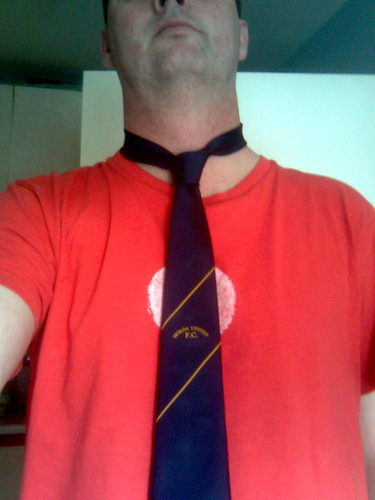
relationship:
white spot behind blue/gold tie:
[145, 265, 243, 334] [119, 122, 247, 500]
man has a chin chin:
[0, 0, 371, 498] [132, 46, 233, 92]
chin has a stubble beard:
[132, 46, 233, 92] [138, 71, 183, 86]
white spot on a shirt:
[145, 259, 237, 331] [2, 156, 372, 498]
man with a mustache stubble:
[0, 0, 371, 498] [137, 6, 208, 36]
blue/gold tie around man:
[119, 122, 247, 500] [0, 0, 371, 498]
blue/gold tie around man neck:
[119, 122, 247, 500] [99, 74, 268, 187]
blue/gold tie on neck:
[119, 122, 247, 500] [121, 92, 247, 171]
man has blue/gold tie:
[0, 0, 371, 498] [119, 122, 247, 500]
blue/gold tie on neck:
[119, 122, 247, 500] [119, 86, 259, 167]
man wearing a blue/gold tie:
[0, 0, 371, 498] [119, 122, 247, 500]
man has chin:
[0, 0, 371, 498] [135, 32, 235, 133]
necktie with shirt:
[124, 117, 250, 498] [2, 156, 372, 498]